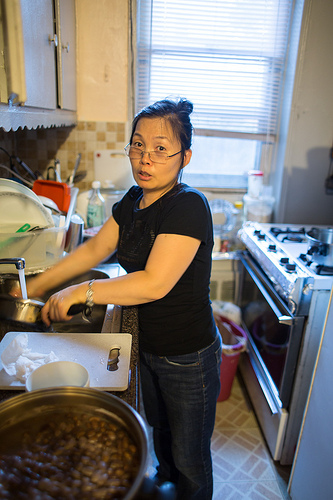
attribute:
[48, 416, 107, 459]
beans — brown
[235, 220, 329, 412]
oven — black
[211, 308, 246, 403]
garbage bin — pink 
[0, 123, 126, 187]
tile — brown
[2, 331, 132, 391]
cutting board — white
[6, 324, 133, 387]
board — white 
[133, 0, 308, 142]
blinds — white 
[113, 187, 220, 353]
shirt — black 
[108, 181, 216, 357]
shirt — black 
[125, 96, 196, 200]
woman — washing 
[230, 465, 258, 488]
tile — patterned 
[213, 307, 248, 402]
bin — red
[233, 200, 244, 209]
lid — yellow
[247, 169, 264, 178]
lid — red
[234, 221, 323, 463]
stove — white 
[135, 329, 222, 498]
jeans — blue 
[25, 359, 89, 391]
container — white 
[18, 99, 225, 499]
woman — washing , standing 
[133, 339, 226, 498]
jeans — blue